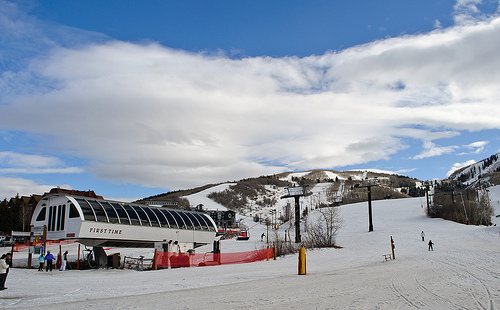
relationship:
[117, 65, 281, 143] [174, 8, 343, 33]
cloud in blue sky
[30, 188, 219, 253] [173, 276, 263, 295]
building in snow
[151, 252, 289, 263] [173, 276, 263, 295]
fence upright in snow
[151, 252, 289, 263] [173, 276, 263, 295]
red netting running across snow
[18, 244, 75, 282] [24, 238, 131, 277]
people standing in snow in front of building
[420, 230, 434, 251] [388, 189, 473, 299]
group of people skiing down snow slope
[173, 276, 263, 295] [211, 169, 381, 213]
snow covered mountain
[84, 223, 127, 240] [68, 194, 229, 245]
words on side of building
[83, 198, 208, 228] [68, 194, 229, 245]
row of windows on top of building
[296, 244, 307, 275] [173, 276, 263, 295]
yellow pole in snow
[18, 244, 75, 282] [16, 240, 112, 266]
group of people in line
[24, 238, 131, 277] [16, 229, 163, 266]
entrance to a sky lift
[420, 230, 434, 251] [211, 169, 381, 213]
group of people riding down a mountain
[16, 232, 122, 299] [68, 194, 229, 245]
line of people at ski lift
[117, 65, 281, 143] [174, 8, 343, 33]
cloud blue blue sky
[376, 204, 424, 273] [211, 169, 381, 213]
snowy ski mountain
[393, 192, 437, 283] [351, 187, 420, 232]
group of people riding slopes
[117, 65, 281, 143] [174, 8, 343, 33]
cloud in a blue sky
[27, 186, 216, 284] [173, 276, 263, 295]
building in snow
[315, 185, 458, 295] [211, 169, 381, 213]
this is a mountain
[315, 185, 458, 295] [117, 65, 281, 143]
this is a cloud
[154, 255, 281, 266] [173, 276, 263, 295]
red fence in snow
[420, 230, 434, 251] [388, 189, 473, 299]
group of people down slope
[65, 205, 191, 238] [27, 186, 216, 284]
white and black building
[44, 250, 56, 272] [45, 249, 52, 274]
line of people wearing a blue jacket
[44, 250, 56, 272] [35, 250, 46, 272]
line of people wearing an aqua jacket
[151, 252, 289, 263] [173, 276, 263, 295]
fence on snow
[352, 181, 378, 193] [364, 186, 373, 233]
light on black pole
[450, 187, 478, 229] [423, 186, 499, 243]
tree with no leaves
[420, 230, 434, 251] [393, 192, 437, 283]
group of people skiing on hill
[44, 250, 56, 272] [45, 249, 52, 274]
line of people wearing white jacket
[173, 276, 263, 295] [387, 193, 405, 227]
snow covered hill top